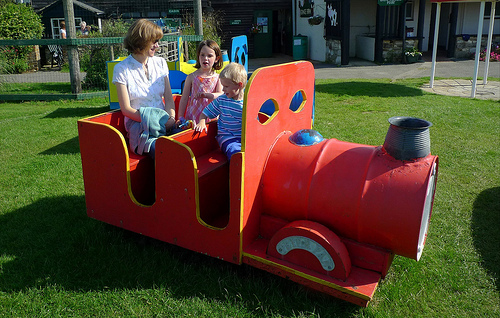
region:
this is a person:
[120, 16, 168, 112]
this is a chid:
[187, 32, 214, 107]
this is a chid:
[212, 65, 244, 137]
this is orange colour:
[100, 151, 120, 199]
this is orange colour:
[256, 123, 284, 185]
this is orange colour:
[160, 160, 170, 220]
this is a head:
[125, 16, 162, 46]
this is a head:
[221, 60, 241, 95]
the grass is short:
[4, 120, 29, 165]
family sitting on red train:
[79, 15, 421, 289]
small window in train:
[255, 93, 280, 122]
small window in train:
[287, 81, 307, 108]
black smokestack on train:
[382, 108, 441, 168]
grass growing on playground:
[12, 84, 397, 304]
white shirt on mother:
[107, 52, 175, 113]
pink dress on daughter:
[179, 71, 219, 121]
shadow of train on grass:
[2, 204, 218, 316]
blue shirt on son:
[207, 97, 252, 159]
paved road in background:
[16, 61, 498, 78]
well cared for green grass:
[336, 90, 373, 110]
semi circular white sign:
[265, 234, 342, 263]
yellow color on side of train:
[283, 265, 365, 292]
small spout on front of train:
[372, 107, 447, 156]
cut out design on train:
[258, 88, 330, 126]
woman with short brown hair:
[121, 17, 169, 55]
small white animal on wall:
[308, 3, 366, 29]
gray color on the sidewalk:
[346, 62, 446, 84]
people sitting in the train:
[67, 14, 283, 179]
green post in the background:
[6, 25, 66, 54]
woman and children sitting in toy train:
[77, 18, 437, 310]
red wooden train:
[75, 57, 439, 307]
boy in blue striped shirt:
[191, 62, 246, 156]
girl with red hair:
[176, 39, 222, 124]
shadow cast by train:
[2, 193, 349, 316]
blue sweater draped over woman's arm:
[127, 109, 169, 156]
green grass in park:
[3, 78, 498, 315]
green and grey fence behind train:
[5, 36, 193, 98]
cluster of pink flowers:
[472, 46, 499, 64]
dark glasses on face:
[149, 36, 159, 46]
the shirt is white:
[122, 57, 169, 104]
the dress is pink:
[194, 77, 214, 115]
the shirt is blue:
[208, 96, 235, 143]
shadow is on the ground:
[325, 75, 419, 105]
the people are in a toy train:
[119, 29, 246, 174]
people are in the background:
[56, 21, 88, 40]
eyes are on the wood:
[259, 95, 310, 129]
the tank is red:
[274, 149, 394, 214]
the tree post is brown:
[59, 4, 91, 98]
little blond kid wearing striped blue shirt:
[194, 64, 248, 159]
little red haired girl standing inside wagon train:
[181, 36, 228, 125]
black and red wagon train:
[80, 57, 441, 311]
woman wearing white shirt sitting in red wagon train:
[116, 20, 178, 146]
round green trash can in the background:
[289, 31, 310, 64]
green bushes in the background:
[0, 1, 41, 69]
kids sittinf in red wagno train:
[175, 40, 248, 157]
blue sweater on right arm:
[130, 102, 175, 155]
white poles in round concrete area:
[426, 3, 497, 91]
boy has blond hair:
[191, 63, 247, 159]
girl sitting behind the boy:
[176, 38, 221, 133]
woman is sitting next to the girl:
[106, 17, 178, 159]